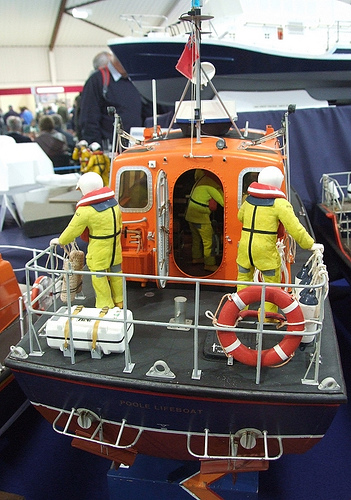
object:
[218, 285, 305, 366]
lifesaver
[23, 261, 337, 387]
guardrail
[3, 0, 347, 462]
boat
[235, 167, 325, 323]
worker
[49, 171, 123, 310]
man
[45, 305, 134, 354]
white case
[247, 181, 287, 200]
life vest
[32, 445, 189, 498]
floor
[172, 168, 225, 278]
door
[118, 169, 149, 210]
window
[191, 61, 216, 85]
speaker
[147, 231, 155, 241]
handles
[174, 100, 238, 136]
blue box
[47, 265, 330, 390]
deck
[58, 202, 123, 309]
crew suit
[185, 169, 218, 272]
man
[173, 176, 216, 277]
galley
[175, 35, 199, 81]
flag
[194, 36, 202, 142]
pole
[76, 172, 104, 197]
helmet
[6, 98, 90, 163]
crowd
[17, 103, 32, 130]
person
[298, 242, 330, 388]
railing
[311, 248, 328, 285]
rope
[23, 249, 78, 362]
rail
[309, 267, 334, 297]
metal ring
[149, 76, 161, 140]
vase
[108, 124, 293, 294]
cabin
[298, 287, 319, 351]
bag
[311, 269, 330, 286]
handle